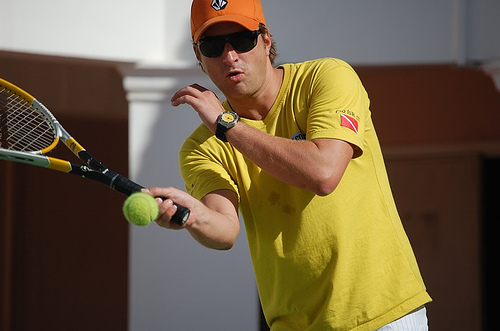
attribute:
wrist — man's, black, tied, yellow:
[214, 114, 240, 143]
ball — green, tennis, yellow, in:
[125, 190, 161, 228]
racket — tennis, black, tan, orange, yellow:
[1, 79, 192, 228]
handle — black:
[114, 163, 192, 225]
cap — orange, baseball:
[193, 3, 266, 50]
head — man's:
[192, 22, 273, 104]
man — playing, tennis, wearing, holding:
[145, 1, 428, 329]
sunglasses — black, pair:
[193, 29, 260, 57]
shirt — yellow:
[179, 50, 435, 330]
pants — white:
[355, 307, 431, 330]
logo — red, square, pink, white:
[337, 116, 363, 134]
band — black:
[217, 122, 226, 141]